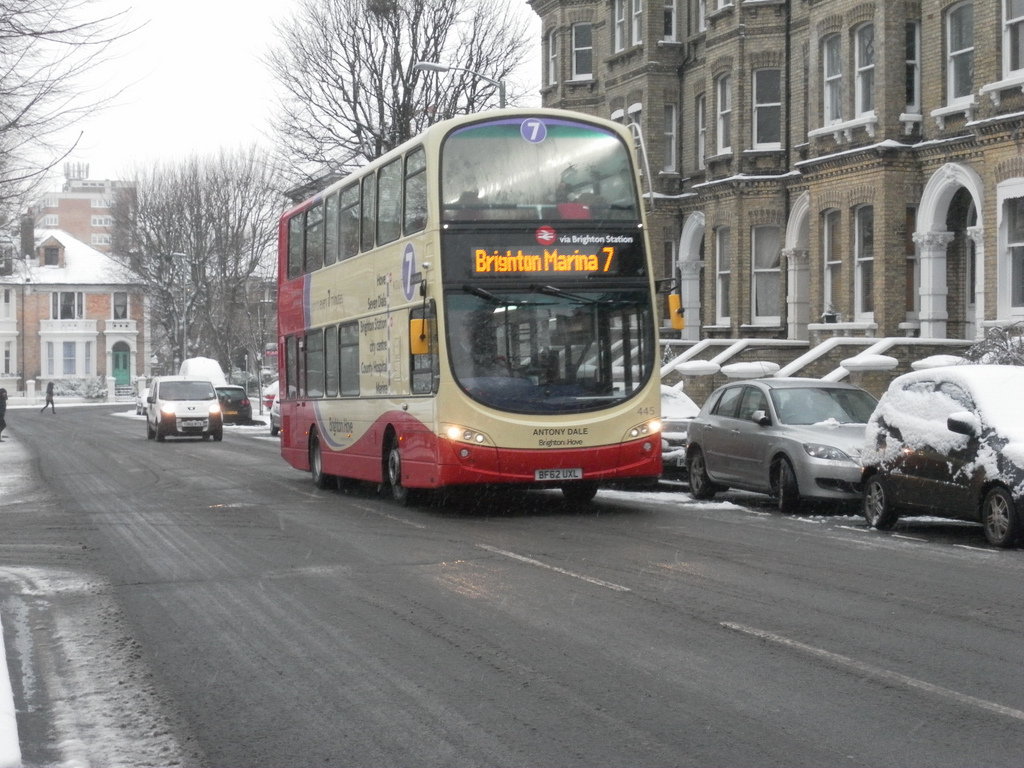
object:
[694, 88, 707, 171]
window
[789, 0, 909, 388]
brownstone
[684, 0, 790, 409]
brownstone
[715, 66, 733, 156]
window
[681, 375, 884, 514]
car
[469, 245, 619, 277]
sign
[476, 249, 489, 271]
letter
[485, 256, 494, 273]
letter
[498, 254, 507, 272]
letter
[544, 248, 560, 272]
letter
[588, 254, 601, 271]
letter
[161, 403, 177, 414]
headlight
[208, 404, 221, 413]
headlight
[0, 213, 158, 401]
building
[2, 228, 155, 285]
roof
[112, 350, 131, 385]
door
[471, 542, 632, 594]
line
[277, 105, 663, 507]
bus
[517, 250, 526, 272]
letters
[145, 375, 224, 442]
van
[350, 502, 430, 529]
line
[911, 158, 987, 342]
arch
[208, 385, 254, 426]
car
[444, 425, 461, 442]
headlight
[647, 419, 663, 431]
light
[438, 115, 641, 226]
windshield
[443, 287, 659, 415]
windshield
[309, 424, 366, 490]
wheel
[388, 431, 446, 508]
wheel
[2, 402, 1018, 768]
road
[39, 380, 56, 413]
person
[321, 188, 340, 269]
window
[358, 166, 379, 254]
window